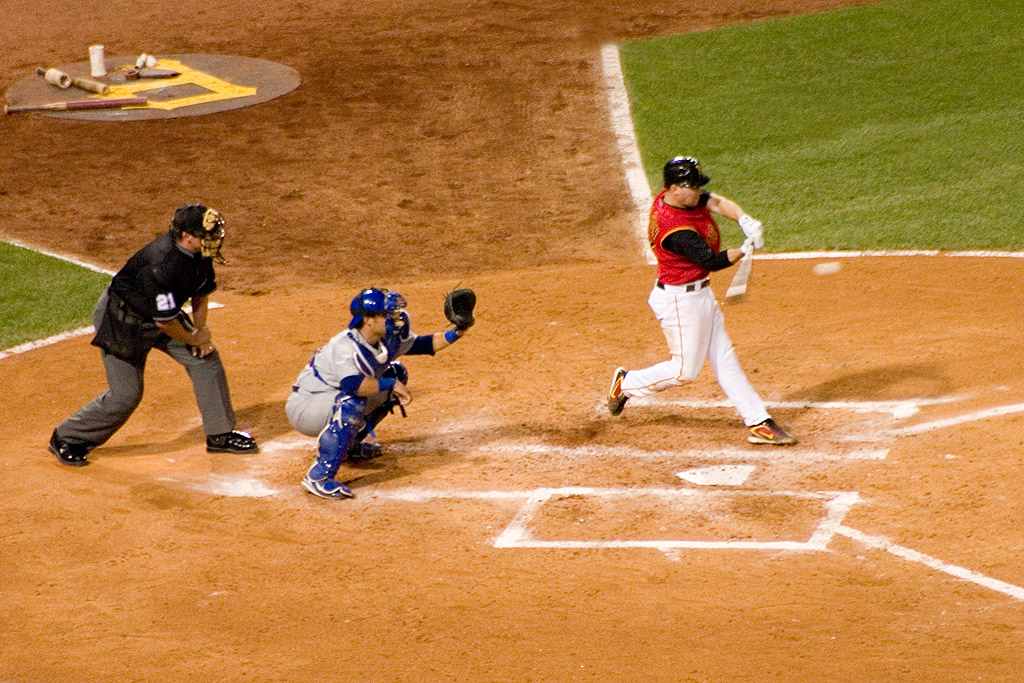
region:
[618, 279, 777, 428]
Man wearing pants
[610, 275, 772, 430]
Man wearing white pants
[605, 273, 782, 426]
Man is wearing white pants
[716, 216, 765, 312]
Man holding a bat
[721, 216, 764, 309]
Man is holding a bat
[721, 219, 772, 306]
Man holding a baseball bat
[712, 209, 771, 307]
Man is holding a baseball bat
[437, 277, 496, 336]
Man wearing a catcher's mitt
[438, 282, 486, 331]
Man is wearing a catcher's mitt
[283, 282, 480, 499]
baseball catcher wearing gray and blue uniform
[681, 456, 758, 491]
white baseball base covered with dirt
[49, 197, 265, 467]
baseball umpire wearing black shirt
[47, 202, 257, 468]
baseball umpire wearing gray pants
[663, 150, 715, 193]
black helmet on head of baseball player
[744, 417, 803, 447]
brown sneaker with red flame design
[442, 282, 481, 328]
brown mitt on hand of baseball player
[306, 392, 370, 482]
blue plastic shin guard on right leg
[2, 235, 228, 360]
small patch of green grass behind umpire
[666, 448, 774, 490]
Home plate is on the ground.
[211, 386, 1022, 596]
White chalk is on the ground.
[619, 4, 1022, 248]
The grass is green.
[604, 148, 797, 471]
Player is holding a bat.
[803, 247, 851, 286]
Ball is in front of the bat.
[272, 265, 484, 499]
The catcher is squatting.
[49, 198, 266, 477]
Umpire is behind the catcher.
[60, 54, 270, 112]
Yellow paint is on the ground.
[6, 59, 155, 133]
Bats are on the ground.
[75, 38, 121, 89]
White container is by the bat.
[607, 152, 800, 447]
Baseball player swinging bat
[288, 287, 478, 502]
Catcher wearing catching glove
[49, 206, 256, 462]
Umpire is wearing mask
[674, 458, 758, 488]
Home plate is dirty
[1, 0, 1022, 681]
White lines on field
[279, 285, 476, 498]
Catcher wearing blue helmit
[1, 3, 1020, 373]
Grass is on field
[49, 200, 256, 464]
Umpire wearing gray pants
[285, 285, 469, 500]
Catcher wearing wrist bands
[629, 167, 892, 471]
a man swinging a bat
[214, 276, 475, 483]
a man wearing a mit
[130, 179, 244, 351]
an umpire wearing a vest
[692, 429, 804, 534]
a white home plate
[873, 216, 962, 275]
white lines on the field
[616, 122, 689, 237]
a ma nwearing a black helmet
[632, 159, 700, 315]
a man wearing a red jersey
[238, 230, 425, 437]
a man wearing a blue face plate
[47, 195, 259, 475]
baseball umpire on baseball field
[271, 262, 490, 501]
baseball catcher on baseball field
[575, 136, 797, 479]
baseball hitter on baseball field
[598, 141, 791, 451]
baseball batter on baseball field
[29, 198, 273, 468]
umpire on baseball field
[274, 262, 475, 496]
catcher on baseball field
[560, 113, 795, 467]
batter on baseball field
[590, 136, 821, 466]
batter swinging bat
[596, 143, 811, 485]
A batter with a red jersey on.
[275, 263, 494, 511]
A catcher with blue gear on.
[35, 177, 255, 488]
An umpire wearing black gear.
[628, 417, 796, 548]
A home plate in baseball.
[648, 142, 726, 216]
A man wearing a black helmet.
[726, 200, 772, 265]
A man wearing white batting gloves.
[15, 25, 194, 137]
Some baseball gear laying on a cement circle in the background.